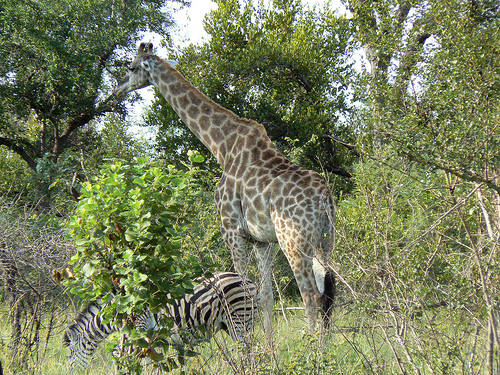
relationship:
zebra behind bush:
[57, 270, 260, 375] [55, 149, 223, 375]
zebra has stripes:
[57, 270, 260, 375] [170, 272, 257, 336]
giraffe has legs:
[114, 41, 343, 340] [220, 223, 340, 340]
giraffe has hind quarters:
[114, 41, 343, 340] [286, 164, 335, 230]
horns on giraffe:
[136, 42, 155, 57] [114, 41, 343, 340]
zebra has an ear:
[57, 270, 260, 375] [67, 327, 75, 341]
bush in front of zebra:
[55, 149, 223, 375] [57, 270, 260, 375]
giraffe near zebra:
[114, 41, 343, 340] [57, 270, 260, 375]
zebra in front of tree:
[57, 270, 260, 375] [139, 2, 353, 190]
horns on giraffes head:
[136, 42, 155, 57] [111, 55, 162, 99]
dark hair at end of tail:
[320, 272, 336, 325] [325, 185, 337, 318]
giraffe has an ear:
[114, 41, 343, 340] [140, 61, 153, 72]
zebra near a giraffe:
[57, 270, 260, 375] [114, 41, 343, 340]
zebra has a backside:
[57, 270, 260, 375] [211, 274, 259, 326]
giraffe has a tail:
[114, 41, 343, 340] [325, 185, 337, 318]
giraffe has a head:
[114, 41, 343, 340] [111, 55, 162, 99]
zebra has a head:
[57, 270, 260, 375] [65, 322, 98, 375]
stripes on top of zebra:
[170, 272, 257, 336] [57, 270, 260, 375]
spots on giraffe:
[219, 155, 325, 225] [114, 41, 343, 340]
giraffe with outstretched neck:
[114, 41, 343, 340] [149, 57, 238, 165]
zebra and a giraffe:
[57, 270, 260, 375] [114, 41, 343, 340]